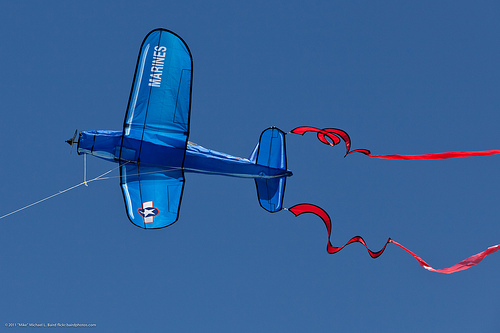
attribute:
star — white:
[137, 203, 160, 219]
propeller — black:
[62, 126, 79, 157]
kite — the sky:
[4, 7, 500, 278]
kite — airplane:
[60, 26, 295, 234]